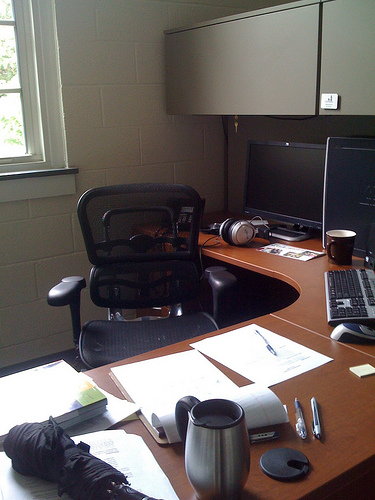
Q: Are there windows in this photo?
A: Yes, there is a window.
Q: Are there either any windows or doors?
A: Yes, there is a window.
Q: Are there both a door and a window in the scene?
A: No, there is a window but no doors.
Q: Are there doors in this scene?
A: No, there are no doors.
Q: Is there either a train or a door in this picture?
A: No, there are no doors or trains.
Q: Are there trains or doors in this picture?
A: No, there are no doors or trains.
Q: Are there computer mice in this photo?
A: Yes, there is a computer mouse.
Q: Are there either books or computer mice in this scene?
A: Yes, there is a computer mouse.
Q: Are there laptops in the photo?
A: No, there are no laptops.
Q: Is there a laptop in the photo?
A: No, there are no laptops.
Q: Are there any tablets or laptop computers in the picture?
A: No, there are no laptop computers or tablets.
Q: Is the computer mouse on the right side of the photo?
A: Yes, the computer mouse is on the right of the image.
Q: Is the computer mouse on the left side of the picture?
A: No, the computer mouse is on the right of the image.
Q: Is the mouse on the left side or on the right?
A: The mouse is on the right of the image.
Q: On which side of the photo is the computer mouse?
A: The computer mouse is on the right of the image.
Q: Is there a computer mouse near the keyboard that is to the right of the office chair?
A: Yes, there is a computer mouse near the keyboard.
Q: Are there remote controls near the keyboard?
A: No, there is a computer mouse near the keyboard.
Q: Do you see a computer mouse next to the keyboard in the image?
A: Yes, there is a computer mouse next to the keyboard.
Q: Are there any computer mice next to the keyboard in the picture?
A: Yes, there is a computer mouse next to the keyboard.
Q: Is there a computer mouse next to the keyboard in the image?
A: Yes, there is a computer mouse next to the keyboard.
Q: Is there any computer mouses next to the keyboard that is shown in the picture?
A: No, there is a computer mouse next to the keyboard.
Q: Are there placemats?
A: No, there are no placemats.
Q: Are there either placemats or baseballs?
A: No, there are no placemats or baseballs.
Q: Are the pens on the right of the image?
A: Yes, the pens are on the right of the image.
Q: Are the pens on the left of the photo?
A: No, the pens are on the right of the image.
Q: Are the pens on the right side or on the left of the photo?
A: The pens are on the right of the image.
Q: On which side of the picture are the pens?
A: The pens are on the right of the image.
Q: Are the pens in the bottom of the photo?
A: Yes, the pens are in the bottom of the image.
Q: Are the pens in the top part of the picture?
A: No, the pens are in the bottom of the image.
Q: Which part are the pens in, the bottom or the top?
A: The pens are in the bottom of the image.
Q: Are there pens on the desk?
A: Yes, there are pens on the desk.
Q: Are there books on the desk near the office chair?
A: No, there are pens on the desk.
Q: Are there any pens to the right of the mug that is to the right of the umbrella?
A: Yes, there are pens to the right of the mug.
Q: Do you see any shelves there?
A: No, there are no shelves.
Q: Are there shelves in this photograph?
A: No, there are no shelves.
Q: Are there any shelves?
A: No, there are no shelves.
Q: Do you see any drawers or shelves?
A: No, there are no shelves or drawers.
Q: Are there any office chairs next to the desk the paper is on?
A: Yes, there is an office chair next to the desk.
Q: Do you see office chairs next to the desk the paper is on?
A: Yes, there is an office chair next to the desk.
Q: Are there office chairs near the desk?
A: Yes, there is an office chair near the desk.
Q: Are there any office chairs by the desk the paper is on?
A: Yes, there is an office chair by the desk.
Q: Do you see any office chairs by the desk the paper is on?
A: Yes, there is an office chair by the desk.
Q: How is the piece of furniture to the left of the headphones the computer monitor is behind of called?
A: The piece of furniture is an office chair.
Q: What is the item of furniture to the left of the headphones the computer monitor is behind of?
A: The piece of furniture is an office chair.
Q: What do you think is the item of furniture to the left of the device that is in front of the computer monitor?
A: The piece of furniture is an office chair.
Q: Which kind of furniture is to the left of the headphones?
A: The piece of furniture is an office chair.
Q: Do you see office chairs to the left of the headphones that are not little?
A: Yes, there is an office chair to the left of the headphones.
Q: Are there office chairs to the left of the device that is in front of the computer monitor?
A: Yes, there is an office chair to the left of the headphones.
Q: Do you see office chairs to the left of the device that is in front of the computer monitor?
A: Yes, there is an office chair to the left of the headphones.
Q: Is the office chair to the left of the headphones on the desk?
A: Yes, the office chair is to the left of the headphones.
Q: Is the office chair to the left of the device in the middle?
A: Yes, the office chair is to the left of the headphones.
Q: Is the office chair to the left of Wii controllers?
A: No, the office chair is to the left of the headphones.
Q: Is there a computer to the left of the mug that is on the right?
A: No, there is an office chair to the left of the mug.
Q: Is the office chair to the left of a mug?
A: Yes, the office chair is to the left of a mug.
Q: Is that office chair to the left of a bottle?
A: No, the office chair is to the left of a mug.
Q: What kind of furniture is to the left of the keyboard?
A: The piece of furniture is an office chair.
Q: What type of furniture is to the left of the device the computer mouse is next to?
A: The piece of furniture is an office chair.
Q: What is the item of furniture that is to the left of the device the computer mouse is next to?
A: The piece of furniture is an office chair.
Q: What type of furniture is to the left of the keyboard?
A: The piece of furniture is an office chair.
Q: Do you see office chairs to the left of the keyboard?
A: Yes, there is an office chair to the left of the keyboard.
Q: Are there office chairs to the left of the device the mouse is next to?
A: Yes, there is an office chair to the left of the keyboard.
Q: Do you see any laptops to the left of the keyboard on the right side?
A: No, there is an office chair to the left of the keyboard.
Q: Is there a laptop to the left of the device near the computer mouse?
A: No, there is an office chair to the left of the keyboard.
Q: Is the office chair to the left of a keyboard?
A: Yes, the office chair is to the left of a keyboard.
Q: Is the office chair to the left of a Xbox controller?
A: No, the office chair is to the left of a keyboard.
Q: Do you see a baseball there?
A: No, there are no baseballs.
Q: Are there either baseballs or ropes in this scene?
A: No, there are no baseballs or ropes.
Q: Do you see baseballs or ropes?
A: No, there are no baseballs or ropes.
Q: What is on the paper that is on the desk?
A: The pen is on the paper.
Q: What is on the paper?
A: The pen is on the paper.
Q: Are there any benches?
A: No, there are no benches.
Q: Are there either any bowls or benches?
A: No, there are no benches or bowls.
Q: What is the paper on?
A: The paper is on the desk.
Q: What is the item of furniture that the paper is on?
A: The piece of furniture is a desk.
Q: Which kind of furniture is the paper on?
A: The paper is on the desk.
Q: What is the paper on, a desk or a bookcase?
A: The paper is on a desk.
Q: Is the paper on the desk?
A: Yes, the paper is on the desk.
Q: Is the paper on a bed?
A: No, the paper is on the desk.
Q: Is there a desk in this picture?
A: Yes, there is a desk.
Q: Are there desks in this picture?
A: Yes, there is a desk.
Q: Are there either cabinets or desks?
A: Yes, there is a desk.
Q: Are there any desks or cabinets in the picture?
A: Yes, there is a desk.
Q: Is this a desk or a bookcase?
A: This is a desk.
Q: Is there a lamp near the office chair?
A: No, there is a desk near the office chair.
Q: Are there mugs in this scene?
A: Yes, there is a mug.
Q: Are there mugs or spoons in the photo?
A: Yes, there is a mug.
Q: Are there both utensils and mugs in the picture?
A: No, there is a mug but no utensils.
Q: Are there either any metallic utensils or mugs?
A: Yes, there is a metal mug.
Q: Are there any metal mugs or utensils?
A: Yes, there is a metal mug.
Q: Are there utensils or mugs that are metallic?
A: Yes, the mug is metallic.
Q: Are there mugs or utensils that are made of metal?
A: Yes, the mug is made of metal.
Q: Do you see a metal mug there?
A: Yes, there is a metal mug.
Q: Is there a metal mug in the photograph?
A: Yes, there is a metal mug.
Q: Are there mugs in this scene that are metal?
A: Yes, there is a metal mug.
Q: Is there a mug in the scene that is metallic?
A: Yes, there is a mug that is metallic.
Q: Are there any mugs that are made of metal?
A: Yes, there is a mug that is made of metal.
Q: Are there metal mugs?
A: Yes, there is a mug that is made of metal.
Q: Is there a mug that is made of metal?
A: Yes, there is a mug that is made of metal.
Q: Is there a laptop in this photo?
A: No, there are no laptops.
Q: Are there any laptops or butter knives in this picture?
A: No, there are no laptops or butter knives.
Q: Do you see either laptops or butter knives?
A: No, there are no laptops or butter knives.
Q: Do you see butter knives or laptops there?
A: No, there are no laptops or butter knives.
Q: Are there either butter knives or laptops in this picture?
A: No, there are no laptops or butter knives.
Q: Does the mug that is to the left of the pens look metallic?
A: Yes, the mug is metallic.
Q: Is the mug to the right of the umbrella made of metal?
A: Yes, the mug is made of metal.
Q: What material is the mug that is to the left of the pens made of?
A: The mug is made of metal.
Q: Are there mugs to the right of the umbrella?
A: Yes, there is a mug to the right of the umbrella.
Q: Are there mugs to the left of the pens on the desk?
A: Yes, there is a mug to the left of the pens.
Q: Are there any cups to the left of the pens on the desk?
A: No, there is a mug to the left of the pens.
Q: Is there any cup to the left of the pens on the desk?
A: No, there is a mug to the left of the pens.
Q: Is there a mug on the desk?
A: Yes, there is a mug on the desk.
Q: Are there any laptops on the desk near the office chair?
A: No, there is a mug on the desk.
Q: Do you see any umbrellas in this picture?
A: Yes, there is an umbrella.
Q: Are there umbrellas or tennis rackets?
A: Yes, there is an umbrella.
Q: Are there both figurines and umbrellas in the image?
A: No, there is an umbrella but no figurines.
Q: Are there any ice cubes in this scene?
A: No, there are no ice cubes.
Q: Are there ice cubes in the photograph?
A: No, there are no ice cubes.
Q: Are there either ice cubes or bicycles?
A: No, there are no ice cubes or bicycles.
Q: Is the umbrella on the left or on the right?
A: The umbrella is on the left of the image.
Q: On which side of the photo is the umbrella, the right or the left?
A: The umbrella is on the left of the image.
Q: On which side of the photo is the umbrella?
A: The umbrella is on the left of the image.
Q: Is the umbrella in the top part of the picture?
A: No, the umbrella is in the bottom of the image.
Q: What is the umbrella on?
A: The umbrella is on the desk.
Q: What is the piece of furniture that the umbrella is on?
A: The piece of furniture is a desk.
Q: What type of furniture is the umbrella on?
A: The umbrella is on the desk.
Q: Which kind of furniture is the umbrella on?
A: The umbrella is on the desk.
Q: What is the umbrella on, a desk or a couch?
A: The umbrella is on a desk.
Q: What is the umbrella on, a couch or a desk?
A: The umbrella is on a desk.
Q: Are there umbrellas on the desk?
A: Yes, there is an umbrella on the desk.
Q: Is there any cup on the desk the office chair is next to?
A: No, there is an umbrella on the desk.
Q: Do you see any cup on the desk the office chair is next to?
A: No, there is an umbrella on the desk.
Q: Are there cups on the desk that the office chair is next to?
A: No, there is an umbrella on the desk.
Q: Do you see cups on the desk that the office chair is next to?
A: No, there is an umbrella on the desk.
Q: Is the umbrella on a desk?
A: Yes, the umbrella is on a desk.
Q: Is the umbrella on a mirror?
A: No, the umbrella is on a desk.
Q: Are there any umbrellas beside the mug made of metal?
A: Yes, there is an umbrella beside the mug.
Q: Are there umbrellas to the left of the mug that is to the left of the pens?
A: Yes, there is an umbrella to the left of the mug.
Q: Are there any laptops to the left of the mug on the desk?
A: No, there is an umbrella to the left of the mug.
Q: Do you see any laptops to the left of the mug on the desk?
A: No, there is an umbrella to the left of the mug.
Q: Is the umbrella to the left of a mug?
A: Yes, the umbrella is to the left of a mug.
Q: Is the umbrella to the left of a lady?
A: No, the umbrella is to the left of a mug.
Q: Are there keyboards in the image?
A: Yes, there is a keyboard.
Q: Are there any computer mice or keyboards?
A: Yes, there is a keyboard.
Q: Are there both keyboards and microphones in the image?
A: No, there is a keyboard but no microphones.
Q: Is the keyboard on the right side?
A: Yes, the keyboard is on the right of the image.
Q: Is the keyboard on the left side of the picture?
A: No, the keyboard is on the right of the image.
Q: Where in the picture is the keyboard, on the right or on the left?
A: The keyboard is on the right of the image.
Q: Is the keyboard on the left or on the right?
A: The keyboard is on the right of the image.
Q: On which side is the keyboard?
A: The keyboard is on the right of the image.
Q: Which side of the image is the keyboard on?
A: The keyboard is on the right of the image.